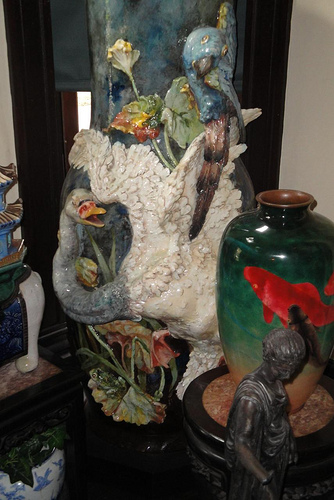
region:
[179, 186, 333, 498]
A green vase sitting on a small round table.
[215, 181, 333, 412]
A green vase with a fish on it.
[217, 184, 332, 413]
A green vase with a red fish on it.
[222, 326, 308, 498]
A bronze statue of a person.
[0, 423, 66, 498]
White and blue pot with ivy in it.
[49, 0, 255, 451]
A piece of art featuring different birds.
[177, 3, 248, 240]
A parrot.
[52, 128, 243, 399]
A goose.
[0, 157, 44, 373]
Artwork including a pagoda.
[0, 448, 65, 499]
White and blue pot.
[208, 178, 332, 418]
a green, red, and brown ceramic vase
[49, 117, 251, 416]
a blue, white, and yellow ceramic goose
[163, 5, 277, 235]
a blue and brown ceramic tropical bird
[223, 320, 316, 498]
a brown statue of a woman looking down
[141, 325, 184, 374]
an orange ceramic goose foot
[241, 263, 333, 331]
a dark red painting of a koi goldfish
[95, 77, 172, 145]
a green, yellow, and red ceramic leaf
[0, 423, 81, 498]
a blue and white ceramic pot with green English ivy growing out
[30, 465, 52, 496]
painting of a blue bird on a white ceramic pot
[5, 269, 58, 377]
white ceramic leg of a small sculpture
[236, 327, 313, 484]
a bronze statue of a person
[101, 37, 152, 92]
a flower on a piece of artwork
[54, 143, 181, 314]
a goose on a piece of artwork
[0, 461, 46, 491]
broken pottery planter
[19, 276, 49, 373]
a white painted table leg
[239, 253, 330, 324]
a red fish on a vase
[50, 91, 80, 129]
the wood frame of a window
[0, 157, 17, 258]
Asian style artwork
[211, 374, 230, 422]
a marble table top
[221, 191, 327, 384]
a green and brown vase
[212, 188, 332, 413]
green vase with red fish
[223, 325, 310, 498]
black statue of person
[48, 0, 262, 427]
large vase with white goose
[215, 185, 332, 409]
green vase has brown rim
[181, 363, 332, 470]
green vase atop black coasters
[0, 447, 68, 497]
white vase with blue designs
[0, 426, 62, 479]
plant growing in white vase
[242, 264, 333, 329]
red fish painted on green vase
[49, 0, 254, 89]
blue shade on window behind large vase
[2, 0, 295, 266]
window with brown wood frame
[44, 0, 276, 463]
large blue vase with parrot and swan design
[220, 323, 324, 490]
black marble statue of Grecian woman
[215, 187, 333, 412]
green ceramic vase with red flowers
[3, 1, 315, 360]
mahogany wooden frame with mirror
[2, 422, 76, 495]
blue and white pot with green pot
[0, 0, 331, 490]
this is an indoor living room scene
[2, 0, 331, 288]
white walls in background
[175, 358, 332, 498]
wood and marble stand under green vase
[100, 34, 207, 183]
green and yellow lilly pad design next to parrot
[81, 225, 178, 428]
yellow and red flowers with green stems